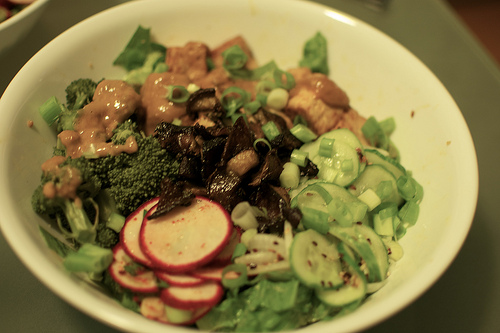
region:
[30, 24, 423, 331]
the food in the bowl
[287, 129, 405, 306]
the pile of sliced cucumbers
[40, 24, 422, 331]
the green onions in the bowl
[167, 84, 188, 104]
the slice of green onion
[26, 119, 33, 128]
the small spot of sauce on the bowl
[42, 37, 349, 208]
the sauce in the bowl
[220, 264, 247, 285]
the slice of green onion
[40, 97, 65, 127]
the slice of green onion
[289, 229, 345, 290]
the slice of cucumber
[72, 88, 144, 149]
the good looking vegtable salad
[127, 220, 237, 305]
the red relish in the plate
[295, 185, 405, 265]
the green cucumber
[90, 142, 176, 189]
the green raw broccoli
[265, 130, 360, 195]
the small chopped onions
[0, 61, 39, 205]
the white dotted bowl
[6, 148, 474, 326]
the white round bowl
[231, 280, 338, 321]
the green chopped lettuce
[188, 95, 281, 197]
the dark colored leafs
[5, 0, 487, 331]
a bowl with salad and meat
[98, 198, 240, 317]
slices of radish on side the dish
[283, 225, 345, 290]
a slice of green cucumber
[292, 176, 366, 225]
a slice of green cucumber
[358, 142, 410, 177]
a slice of green cucumber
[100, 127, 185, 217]
a piece of broccoli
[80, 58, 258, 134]
red meat with sauce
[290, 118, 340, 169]
slices of onion oxtail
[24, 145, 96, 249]
broccoli covered with sauce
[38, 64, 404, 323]
salad in the bowl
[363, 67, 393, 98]
the bowl is white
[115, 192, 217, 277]
onions in the bowl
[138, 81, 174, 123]
meat in the salad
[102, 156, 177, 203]
head of the broccoli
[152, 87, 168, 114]
the sauce is brown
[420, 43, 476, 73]
the table is green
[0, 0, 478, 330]
a white bowl on a green mat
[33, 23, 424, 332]
a salad in a white bowl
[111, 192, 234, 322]
slices of radish in a salad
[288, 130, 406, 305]
slices of cucumber in a salad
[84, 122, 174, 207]
a broccoli head in a salad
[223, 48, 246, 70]
a chopped green onion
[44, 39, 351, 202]
brown vinaigrette in a salad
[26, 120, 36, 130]
a bit of vinaigrette on the side of a bowl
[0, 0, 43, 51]
edge of a bowl containing food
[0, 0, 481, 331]
a white bowl with a raw veggie salad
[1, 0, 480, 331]
Round white bowl full of food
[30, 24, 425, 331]
Delicious food consisting primarily of green vegetables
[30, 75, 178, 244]
Green broccoli florets in bowl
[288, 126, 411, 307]
Bunch of sliced cucumber or zucchini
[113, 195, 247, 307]
Stack of radish slices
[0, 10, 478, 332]
A bowl full of vegetables.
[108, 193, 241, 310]
Sliced radishes.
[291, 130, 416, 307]
Cucumbers with sesame seeds.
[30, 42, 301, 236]
Broccoli covered with a thick sauce.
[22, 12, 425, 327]
Various vegetables sprinkled with sesame seeds.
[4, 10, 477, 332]
A white bowl.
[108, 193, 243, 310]
Radishes.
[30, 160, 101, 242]
A broccoli florette.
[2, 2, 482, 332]
A bowl holding chopped food.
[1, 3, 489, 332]
A white bowl containing food.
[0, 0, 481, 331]
bowl is white